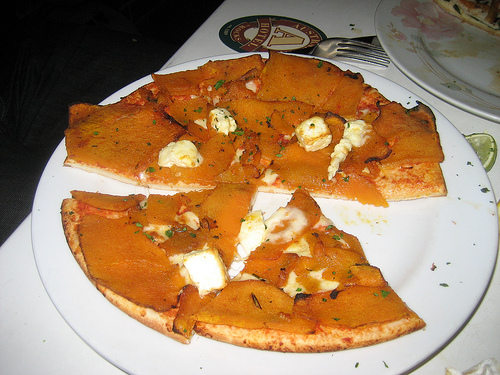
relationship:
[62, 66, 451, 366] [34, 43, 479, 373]
pizza on plate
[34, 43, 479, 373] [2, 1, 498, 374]
plate on table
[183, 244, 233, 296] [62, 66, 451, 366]
topping on pizza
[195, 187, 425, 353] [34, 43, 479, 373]
pizza slice on plate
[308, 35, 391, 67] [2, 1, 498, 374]
fork on table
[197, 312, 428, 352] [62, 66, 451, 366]
crust on pizza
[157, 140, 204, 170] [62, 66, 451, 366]
cheese on pizza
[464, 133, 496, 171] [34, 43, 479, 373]
lime under plate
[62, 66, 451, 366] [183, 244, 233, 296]
pizza has topping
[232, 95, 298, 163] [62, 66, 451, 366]
flakes are on pizza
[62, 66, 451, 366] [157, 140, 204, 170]
pizza has cheese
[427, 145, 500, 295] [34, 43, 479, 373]
flakes are on plate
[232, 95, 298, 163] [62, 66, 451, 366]
flakes are o pizza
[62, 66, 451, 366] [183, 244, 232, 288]
pizza has topping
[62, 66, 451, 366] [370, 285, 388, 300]
pizza has topping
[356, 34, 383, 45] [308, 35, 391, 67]
knife behind a fork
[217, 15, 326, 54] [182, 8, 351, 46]
logo on table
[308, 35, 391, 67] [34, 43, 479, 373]
fork between plate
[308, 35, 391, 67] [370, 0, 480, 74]
fork between plate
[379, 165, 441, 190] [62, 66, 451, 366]
sauce on a pizza